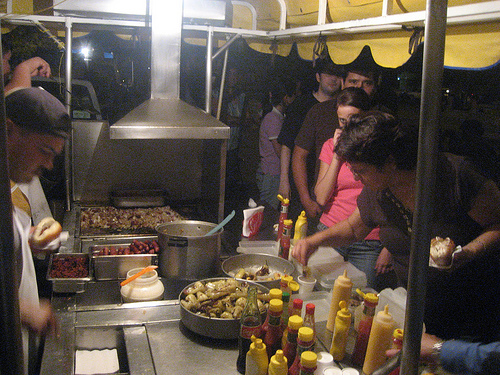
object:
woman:
[290, 107, 497, 342]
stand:
[0, 1, 498, 374]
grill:
[77, 199, 191, 247]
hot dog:
[29, 217, 70, 256]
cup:
[293, 273, 316, 301]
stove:
[56, 268, 233, 296]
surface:
[41, 267, 244, 373]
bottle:
[264, 298, 284, 350]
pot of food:
[152, 210, 225, 284]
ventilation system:
[107, 1, 235, 142]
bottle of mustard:
[294, 209, 309, 236]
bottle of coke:
[234, 280, 269, 371]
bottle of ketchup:
[277, 214, 297, 266]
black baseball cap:
[0, 85, 76, 142]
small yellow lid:
[299, 350, 322, 368]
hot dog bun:
[28, 206, 72, 254]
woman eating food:
[290, 111, 500, 343]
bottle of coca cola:
[233, 280, 268, 374]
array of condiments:
[125, 240, 148, 252]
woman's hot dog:
[428, 235, 461, 273]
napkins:
[235, 198, 266, 238]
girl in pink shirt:
[311, 82, 393, 300]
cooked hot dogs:
[149, 239, 161, 253]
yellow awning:
[0, 1, 499, 72]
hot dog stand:
[0, 1, 499, 375]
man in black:
[5, 78, 89, 142]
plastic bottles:
[361, 302, 397, 375]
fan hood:
[109, 97, 233, 141]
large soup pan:
[148, 211, 228, 281]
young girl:
[310, 84, 396, 290]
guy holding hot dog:
[0, 23, 71, 300]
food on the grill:
[107, 185, 170, 210]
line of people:
[153, 28, 497, 369]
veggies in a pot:
[182, 294, 195, 305]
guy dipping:
[0, 87, 77, 368]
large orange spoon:
[120, 265, 158, 286]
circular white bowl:
[176, 275, 274, 340]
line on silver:
[68, 299, 226, 342]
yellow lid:
[267, 297, 284, 314]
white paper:
[244, 207, 254, 217]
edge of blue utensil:
[202, 208, 236, 235]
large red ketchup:
[259, 296, 287, 358]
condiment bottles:
[328, 301, 353, 360]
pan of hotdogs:
[86, 232, 183, 278]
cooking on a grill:
[82, 134, 214, 239]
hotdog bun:
[426, 234, 463, 267]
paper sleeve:
[424, 244, 470, 274]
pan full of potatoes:
[172, 274, 273, 341]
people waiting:
[163, 27, 497, 338]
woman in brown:
[294, 112, 499, 358]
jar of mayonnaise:
[117, 265, 165, 303]